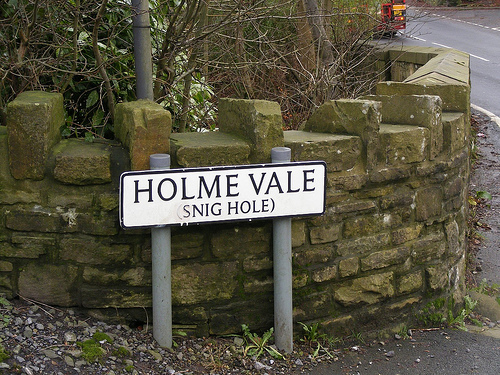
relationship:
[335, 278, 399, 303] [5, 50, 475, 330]
brick on container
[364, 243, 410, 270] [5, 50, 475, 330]
brick on container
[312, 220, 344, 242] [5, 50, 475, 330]
brick on container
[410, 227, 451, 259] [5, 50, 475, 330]
brick on container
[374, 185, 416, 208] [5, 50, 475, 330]
brick on container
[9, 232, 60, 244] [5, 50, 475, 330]
brick on container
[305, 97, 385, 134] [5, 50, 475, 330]
brick on container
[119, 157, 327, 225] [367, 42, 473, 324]
sign in front of wall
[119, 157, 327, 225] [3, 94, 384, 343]
sign in front of wall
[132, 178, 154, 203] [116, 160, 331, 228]
h on sign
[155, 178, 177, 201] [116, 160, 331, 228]
letter o on sign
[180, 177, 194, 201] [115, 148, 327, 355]
l on sign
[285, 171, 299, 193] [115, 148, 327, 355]
l on sign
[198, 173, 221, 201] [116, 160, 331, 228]
letter m on sign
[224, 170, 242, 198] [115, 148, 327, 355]
letter e on sign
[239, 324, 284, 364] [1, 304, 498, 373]
weeds on ground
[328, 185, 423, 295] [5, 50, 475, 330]
brick on container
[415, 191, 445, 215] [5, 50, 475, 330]
brick on container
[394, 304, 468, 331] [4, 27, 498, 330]
brick on container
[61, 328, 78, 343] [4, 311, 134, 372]
pebble on ground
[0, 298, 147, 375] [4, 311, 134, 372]
pebble on ground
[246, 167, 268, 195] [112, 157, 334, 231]
letter v on sign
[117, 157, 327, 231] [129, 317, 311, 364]
sign on ground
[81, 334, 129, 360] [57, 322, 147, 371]
moss on rocks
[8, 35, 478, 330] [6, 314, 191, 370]
rocks on ground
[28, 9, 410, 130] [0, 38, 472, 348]
branches behind wall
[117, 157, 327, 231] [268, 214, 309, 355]
sign on pole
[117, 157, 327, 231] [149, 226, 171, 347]
sign on pole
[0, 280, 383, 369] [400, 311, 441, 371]
rock on floor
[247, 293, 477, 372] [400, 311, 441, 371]
debris on floor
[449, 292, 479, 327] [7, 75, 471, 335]
grass on edge of wall